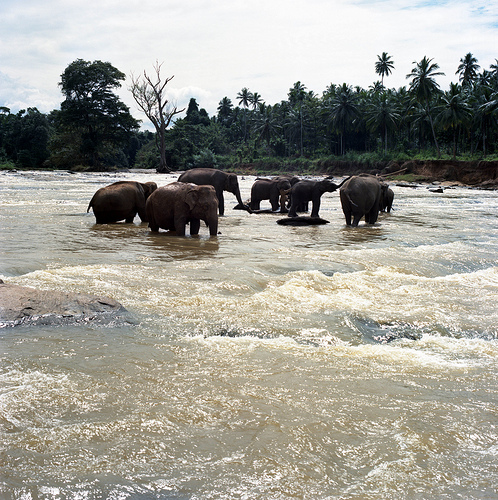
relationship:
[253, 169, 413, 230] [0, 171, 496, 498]
animal in water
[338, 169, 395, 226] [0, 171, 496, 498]
animal in water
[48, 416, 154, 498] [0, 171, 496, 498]
ripple in water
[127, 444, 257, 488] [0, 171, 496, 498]
ripple in water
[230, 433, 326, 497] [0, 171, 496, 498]
ripple in water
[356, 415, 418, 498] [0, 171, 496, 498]
ripple in water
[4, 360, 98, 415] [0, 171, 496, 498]
ripple in water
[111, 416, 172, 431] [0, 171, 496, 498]
ripples in water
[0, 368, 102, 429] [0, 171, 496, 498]
ripples in water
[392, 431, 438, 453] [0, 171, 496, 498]
ripples in water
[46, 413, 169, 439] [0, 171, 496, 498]
ripples in water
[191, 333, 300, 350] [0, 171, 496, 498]
ripples in water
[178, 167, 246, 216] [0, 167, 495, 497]
elephant in river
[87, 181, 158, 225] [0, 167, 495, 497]
elephant in river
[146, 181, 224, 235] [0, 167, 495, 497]
elephant in river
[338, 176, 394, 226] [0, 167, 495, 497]
animal in river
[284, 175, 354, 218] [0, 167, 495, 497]
elephant in river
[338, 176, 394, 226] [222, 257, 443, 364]
animal in river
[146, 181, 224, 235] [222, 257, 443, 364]
elephant in river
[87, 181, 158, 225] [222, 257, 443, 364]
elephant in river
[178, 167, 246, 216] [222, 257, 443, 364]
elephant in river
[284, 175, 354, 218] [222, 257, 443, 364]
elephant in river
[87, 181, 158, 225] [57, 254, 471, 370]
elephant in water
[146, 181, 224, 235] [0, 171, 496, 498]
elephant in water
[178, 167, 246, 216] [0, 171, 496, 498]
elephant in water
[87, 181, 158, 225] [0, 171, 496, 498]
elephant in water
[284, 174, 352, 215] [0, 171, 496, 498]
elephant in water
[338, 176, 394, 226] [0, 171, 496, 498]
animal in water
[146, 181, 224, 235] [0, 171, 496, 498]
elephant standing in water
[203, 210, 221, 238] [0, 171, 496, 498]
elephant trunk in water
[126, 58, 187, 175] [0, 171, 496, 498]
tree in water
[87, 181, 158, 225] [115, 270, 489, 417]
elephant in river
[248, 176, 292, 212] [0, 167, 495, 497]
animal in river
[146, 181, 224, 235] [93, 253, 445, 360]
elephant in river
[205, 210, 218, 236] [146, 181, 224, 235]
elephant trunk belonging to elephant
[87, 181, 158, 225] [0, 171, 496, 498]
elephant standing in water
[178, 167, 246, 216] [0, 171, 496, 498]
elephant standing in water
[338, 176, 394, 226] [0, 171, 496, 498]
animal standing in water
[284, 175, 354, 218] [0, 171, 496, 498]
elephant standing in water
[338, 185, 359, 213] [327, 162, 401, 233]
tail belonging to elephant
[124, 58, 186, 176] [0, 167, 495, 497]
tree growing alongside river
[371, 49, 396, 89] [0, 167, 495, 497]
tree growing alongside river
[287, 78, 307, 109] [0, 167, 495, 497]
tree growing alongside river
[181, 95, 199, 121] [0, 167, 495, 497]
tree growing alongside river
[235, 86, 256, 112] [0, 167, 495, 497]
tree growing alongside river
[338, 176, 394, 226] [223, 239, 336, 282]
animal standing in river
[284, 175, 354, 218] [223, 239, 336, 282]
elephant standing in river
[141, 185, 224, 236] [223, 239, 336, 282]
elephant standing in river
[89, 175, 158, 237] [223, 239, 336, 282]
elephant standing in river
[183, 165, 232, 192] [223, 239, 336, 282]
elephant standing in river